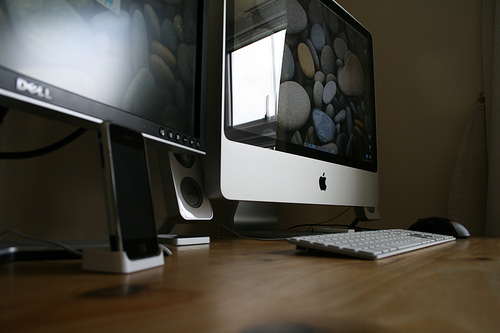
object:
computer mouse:
[409, 218, 469, 240]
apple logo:
[318, 172, 328, 192]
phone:
[91, 118, 164, 262]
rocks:
[282, 45, 353, 153]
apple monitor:
[221, 0, 382, 208]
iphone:
[95, 98, 185, 267]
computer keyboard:
[281, 228, 456, 260]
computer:
[0, 3, 473, 275]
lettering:
[13, 77, 52, 100]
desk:
[2, 235, 500, 331]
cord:
[0, 122, 98, 161]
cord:
[0, 230, 82, 258]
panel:
[155, 129, 201, 148]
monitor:
[4, 3, 210, 157]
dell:
[16, 77, 52, 100]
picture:
[218, 16, 377, 164]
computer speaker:
[160, 147, 215, 244]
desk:
[246, 255, 346, 307]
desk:
[171, 204, 496, 331]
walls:
[0, 1, 499, 245]